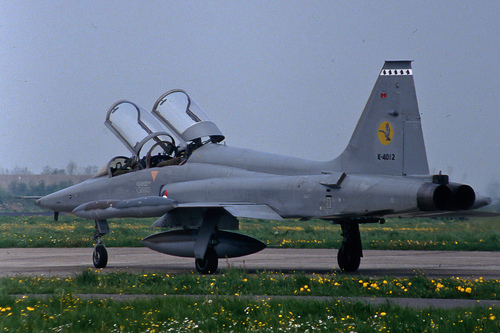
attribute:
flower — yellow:
[381, 279, 388, 284]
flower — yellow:
[461, 286, 473, 293]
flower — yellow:
[487, 312, 496, 320]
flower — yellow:
[301, 281, 309, 288]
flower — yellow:
[26, 305, 34, 310]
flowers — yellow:
[276, 274, 361, 292]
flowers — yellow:
[293, 279, 323, 301]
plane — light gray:
[37, 63, 478, 265]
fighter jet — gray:
[12, 45, 498, 279]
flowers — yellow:
[269, 268, 481, 300]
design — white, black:
[375, 65, 414, 79]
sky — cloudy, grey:
[151, 23, 343, 120]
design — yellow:
[367, 118, 397, 150]